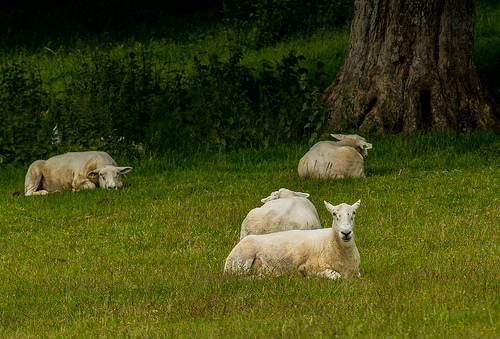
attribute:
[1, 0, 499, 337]
grass — green 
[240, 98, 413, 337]
sheep — white 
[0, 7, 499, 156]
shrubs — distant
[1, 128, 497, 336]
grass — green , full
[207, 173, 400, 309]
sheep — white 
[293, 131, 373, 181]
sheep — lying, white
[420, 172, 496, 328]
grass — white 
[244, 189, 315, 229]
sheep — white 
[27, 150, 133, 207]
sheep — white 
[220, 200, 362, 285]
animal — laying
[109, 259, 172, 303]
grass — green 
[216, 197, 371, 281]
sheep — white 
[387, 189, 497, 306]
grass — green 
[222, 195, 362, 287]
sheep — white 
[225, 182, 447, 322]
cow — white 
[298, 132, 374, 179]
sheep — white 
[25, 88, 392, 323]
sheep — white